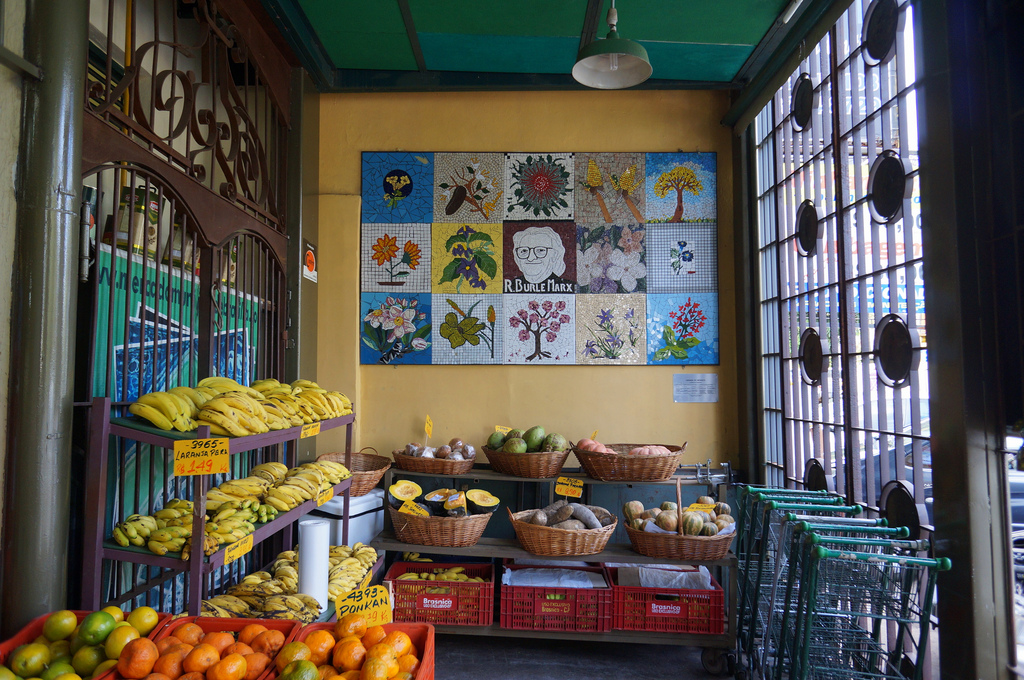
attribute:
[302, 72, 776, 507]
yellow wall — yellow 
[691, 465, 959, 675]
shopping carts — green , silver  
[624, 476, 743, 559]
basket — brown , wicker 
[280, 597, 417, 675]
orange fruit — orange 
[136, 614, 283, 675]
orange fruit — orange 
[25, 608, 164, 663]
fruit — green , yellow 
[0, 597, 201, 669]
basket — red 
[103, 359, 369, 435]
yellow bananas — yellow 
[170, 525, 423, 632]
yellow bananas — yellow 